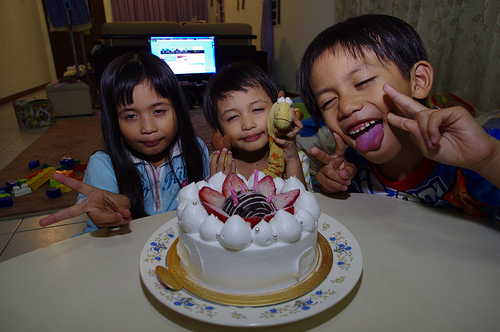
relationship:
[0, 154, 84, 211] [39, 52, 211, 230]
blocks for girl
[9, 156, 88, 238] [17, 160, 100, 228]
blocks on rug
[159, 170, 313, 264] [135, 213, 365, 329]
cake on dish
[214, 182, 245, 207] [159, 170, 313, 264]
candle on cake